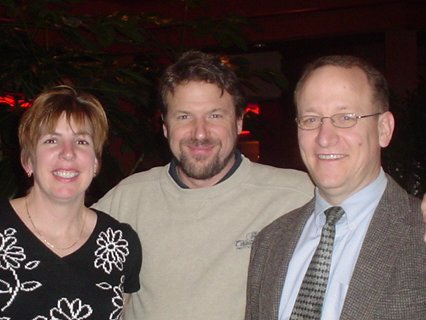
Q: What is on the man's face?
A: Glasses.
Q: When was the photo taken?
A: Night time.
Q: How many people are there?
A: Three.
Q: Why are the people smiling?
A: For the photo.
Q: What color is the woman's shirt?
A: Black.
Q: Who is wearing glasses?
A: The man.